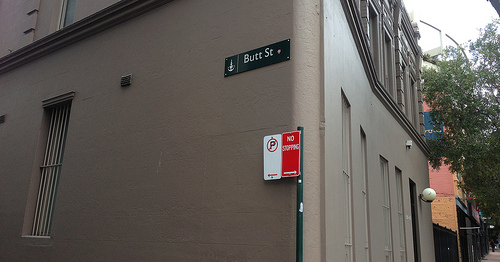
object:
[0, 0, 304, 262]
facade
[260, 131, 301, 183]
sign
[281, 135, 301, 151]
no parking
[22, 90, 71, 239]
window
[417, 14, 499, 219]
leaves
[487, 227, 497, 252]
person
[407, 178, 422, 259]
door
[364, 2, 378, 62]
windows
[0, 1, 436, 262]
building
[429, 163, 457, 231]
brick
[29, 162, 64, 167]
bars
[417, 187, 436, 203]
lamp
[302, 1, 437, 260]
concrete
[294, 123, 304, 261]
pole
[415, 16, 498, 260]
tree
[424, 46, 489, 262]
building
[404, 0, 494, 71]
sky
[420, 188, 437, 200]
circle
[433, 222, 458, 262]
fence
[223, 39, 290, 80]
sign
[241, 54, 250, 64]
letters